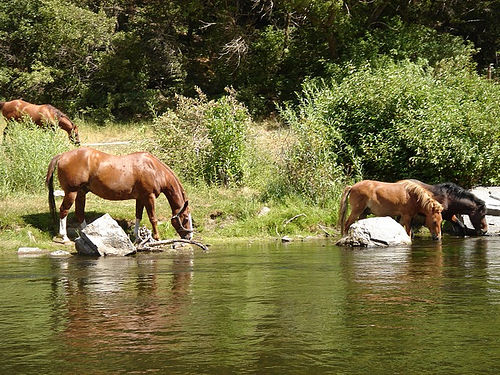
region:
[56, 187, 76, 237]
brown leg of horse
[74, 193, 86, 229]
brown leg of horse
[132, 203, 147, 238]
brown leg of horse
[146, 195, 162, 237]
brown leg of horse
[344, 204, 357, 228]
brown leg of horse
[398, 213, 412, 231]
brown leg of horse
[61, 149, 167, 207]
brown body of horse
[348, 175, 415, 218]
brown body of horse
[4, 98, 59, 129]
brown body of horse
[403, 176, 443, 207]
brown body of horse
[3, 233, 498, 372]
A fresh water lake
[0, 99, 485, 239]
Several horses grazing and drinking water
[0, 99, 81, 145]
A horse grazing on grass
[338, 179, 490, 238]
Two horses drinking water at a lake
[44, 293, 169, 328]
Water ripples in a lake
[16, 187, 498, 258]
Large rocks on the lake shore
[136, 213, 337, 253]
Dead branches near the lake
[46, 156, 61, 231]
A horse's tail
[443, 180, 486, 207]
A horse's mane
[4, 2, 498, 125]
A dense forest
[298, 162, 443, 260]
Horses drinking water from the pond.Horses drinking water from the pond.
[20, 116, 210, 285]
a horse drinking water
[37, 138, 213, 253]
a brown horse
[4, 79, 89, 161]
a horse grazing in the grass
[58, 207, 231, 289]
a rock and a branch next to the water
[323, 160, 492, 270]
two horses drinking water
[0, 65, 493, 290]
four horses in the wilderness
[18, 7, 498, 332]
trees and bushes by the water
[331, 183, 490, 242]
two different brown horses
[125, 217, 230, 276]
a branch floating in the water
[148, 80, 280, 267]
a bush by the river